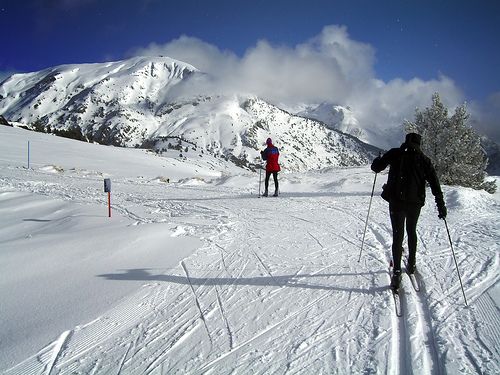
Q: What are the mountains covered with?
A: Snow.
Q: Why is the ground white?
A: Due to snow.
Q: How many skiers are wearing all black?
A: 1.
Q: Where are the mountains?
A: In front of the skier in red.